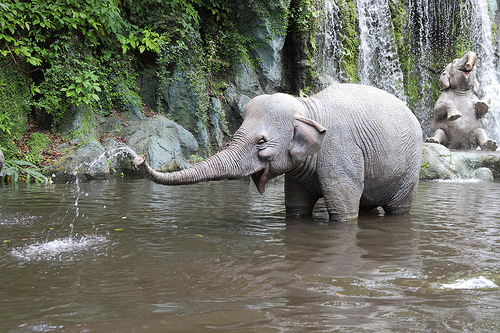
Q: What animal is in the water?
A: An elephant.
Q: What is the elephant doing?
A: Spraying water.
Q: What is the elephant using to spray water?
A: A nose.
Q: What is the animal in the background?
A: An elephant.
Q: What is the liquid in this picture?
A: Water.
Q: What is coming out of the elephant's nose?
A: Water.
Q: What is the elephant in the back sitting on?
A: A rock.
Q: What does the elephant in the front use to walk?
A: Legs.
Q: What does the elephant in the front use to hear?
A: Ears.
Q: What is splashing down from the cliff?
A: Water.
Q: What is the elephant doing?
A: Splashing water.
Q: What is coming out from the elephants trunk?
A: Water.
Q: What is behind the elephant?
A: Waterfall.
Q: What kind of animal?
A: Elephant.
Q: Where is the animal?
A: In the water.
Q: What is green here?
A: The plants.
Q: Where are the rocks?
A: On the wall.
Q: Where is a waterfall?
A: Behind the elephant.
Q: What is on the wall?
A: Plants.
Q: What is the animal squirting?
A: Water.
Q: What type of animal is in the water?
A: An elephant.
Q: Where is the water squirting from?
A: The elephants trunk.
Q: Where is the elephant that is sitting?
A: Under the waterfall.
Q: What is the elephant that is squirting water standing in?
A: A river.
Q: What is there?
A: Elephants.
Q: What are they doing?
A: Bathing.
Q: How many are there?
A: 2.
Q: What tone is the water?
A: Murky.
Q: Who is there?
A: Nobody.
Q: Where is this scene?
A: Watering hole.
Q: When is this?
A: Daytime.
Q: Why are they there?
A: Using water.